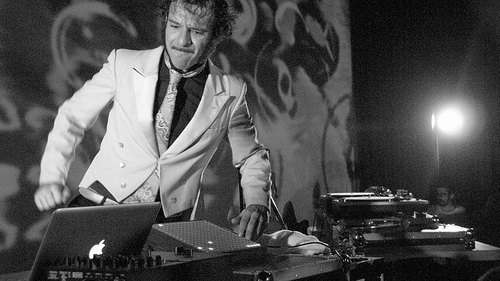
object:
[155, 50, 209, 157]
tie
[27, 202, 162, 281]
laptop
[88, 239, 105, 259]
logo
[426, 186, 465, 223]
person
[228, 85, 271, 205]
arm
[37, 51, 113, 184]
arm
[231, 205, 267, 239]
hand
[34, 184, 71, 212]
hand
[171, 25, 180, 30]
eye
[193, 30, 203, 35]
eye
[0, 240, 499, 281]
desk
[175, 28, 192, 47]
nose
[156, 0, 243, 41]
hair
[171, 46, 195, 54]
moustache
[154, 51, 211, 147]
shirt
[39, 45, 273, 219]
jacket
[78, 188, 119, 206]
belt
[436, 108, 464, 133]
light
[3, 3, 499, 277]
picture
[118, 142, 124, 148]
buttons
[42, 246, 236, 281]
equipment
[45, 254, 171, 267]
many buttons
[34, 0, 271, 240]
man